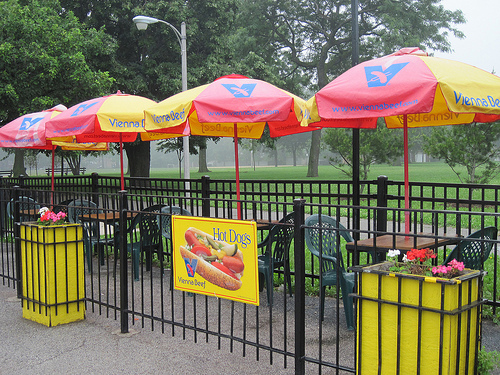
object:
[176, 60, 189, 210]
post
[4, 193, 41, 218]
chairs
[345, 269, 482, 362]
container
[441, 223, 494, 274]
chair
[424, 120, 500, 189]
trees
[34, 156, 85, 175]
bench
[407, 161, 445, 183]
lawn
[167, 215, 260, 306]
advertisement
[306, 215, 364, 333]
chair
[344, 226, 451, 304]
table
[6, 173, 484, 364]
post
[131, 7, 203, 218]
light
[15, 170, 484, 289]
area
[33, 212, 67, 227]
top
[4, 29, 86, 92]
foliage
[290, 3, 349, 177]
trees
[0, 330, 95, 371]
cracks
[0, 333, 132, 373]
paved area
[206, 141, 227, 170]
fog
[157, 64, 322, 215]
umbrella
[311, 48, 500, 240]
umbrella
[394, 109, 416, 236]
pole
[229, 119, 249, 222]
pole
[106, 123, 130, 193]
pole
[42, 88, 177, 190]
umbrella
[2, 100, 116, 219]
umbrella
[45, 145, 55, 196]
pole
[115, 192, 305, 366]
gate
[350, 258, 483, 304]
flower pot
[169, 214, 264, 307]
advertisement sign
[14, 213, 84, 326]
container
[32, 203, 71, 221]
flowers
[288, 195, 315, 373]
fence post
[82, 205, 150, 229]
table top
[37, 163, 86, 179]
bench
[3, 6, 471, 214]
park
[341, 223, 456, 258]
table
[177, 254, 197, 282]
logo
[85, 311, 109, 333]
cracks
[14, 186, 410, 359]
fence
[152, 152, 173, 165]
fog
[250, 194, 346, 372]
rails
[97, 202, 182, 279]
chair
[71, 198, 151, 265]
table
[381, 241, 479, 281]
flowers